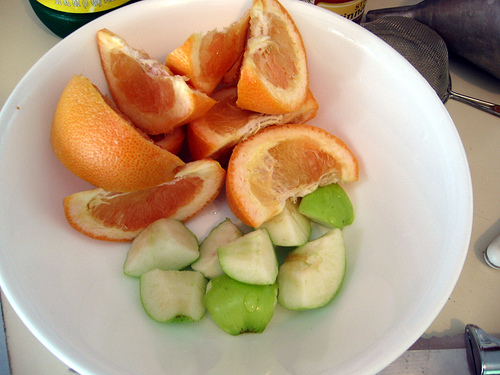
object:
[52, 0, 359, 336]
fruit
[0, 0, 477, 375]
plate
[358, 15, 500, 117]
strainer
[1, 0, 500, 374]
counter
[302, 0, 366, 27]
bottle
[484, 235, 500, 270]
handle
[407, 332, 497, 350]
knife